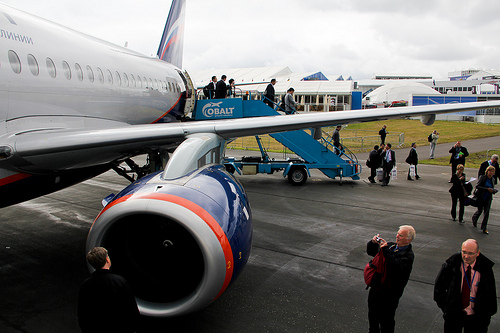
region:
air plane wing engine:
[85, 135, 279, 315]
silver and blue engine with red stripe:
[86, 136, 295, 318]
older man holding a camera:
[357, 218, 430, 321]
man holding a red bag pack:
[364, 226, 412, 296]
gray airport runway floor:
[264, 185, 361, 311]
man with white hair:
[393, 220, 422, 250]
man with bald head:
[459, 233, 485, 269]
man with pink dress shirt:
[452, 254, 494, 329]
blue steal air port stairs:
[196, 82, 366, 188]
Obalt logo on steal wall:
[197, 99, 245, 120]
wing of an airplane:
[0, 95, 499, 180]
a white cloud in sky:
[372, 11, 482, 59]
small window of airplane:
[4, 50, 23, 75]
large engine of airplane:
[80, 133, 274, 319]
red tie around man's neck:
[456, 262, 473, 311]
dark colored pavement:
[299, 220, 355, 255]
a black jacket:
[77, 266, 146, 332]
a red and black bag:
[363, 249, 390, 291]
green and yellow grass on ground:
[446, 125, 471, 138]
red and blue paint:
[182, 183, 217, 207]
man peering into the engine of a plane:
[78, 187, 233, 327]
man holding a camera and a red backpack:
[358, 212, 420, 332]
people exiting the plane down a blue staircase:
[166, 67, 363, 183]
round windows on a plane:
[5, 44, 191, 111]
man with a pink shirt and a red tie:
[432, 240, 492, 332]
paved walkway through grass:
[342, 127, 498, 169]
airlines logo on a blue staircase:
[196, 99, 243, 117]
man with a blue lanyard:
[457, 257, 482, 310]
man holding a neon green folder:
[446, 136, 473, 163]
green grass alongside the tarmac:
[256, 98, 497, 199]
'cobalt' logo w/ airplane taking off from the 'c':
[196, 98, 241, 120]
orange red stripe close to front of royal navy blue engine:
[89, 162, 259, 327]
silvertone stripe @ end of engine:
[81, 197, 224, 319]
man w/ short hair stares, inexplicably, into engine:
[64, 244, 146, 331]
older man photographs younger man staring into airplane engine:
[342, 219, 419, 331]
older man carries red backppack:
[359, 242, 396, 293]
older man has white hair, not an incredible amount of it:
[393, 223, 418, 246]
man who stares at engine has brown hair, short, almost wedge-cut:
[83, 240, 115, 272]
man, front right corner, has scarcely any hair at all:
[431, 233, 498, 331]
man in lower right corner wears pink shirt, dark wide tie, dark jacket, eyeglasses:
[427, 234, 499, 331]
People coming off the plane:
[200, 67, 304, 110]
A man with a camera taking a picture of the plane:
[362, 215, 419, 317]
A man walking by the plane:
[428, 227, 496, 330]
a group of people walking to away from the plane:
[447, 124, 499, 239]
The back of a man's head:
[84, 236, 121, 300]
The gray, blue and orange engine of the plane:
[120, 139, 267, 320]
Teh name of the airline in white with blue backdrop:
[195, 100, 252, 124]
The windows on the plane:
[6, 44, 170, 101]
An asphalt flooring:
[289, 204, 353, 252]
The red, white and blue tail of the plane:
[155, 2, 196, 76]